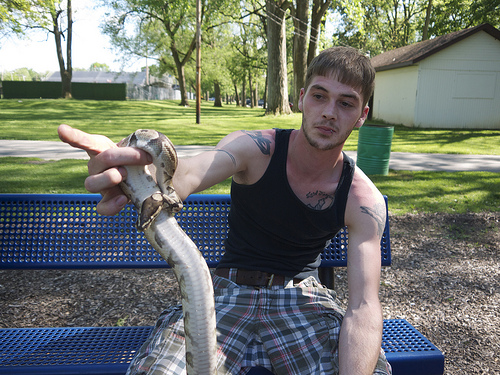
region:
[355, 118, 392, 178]
Green garbage can.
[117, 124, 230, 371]
Snake in man's hand.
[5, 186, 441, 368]
Blue park bench.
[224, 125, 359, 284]
Black tank top on man.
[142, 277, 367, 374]
Plaid shorts on man.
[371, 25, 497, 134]
Tan building in park.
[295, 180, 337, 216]
Tattoo on man's chest.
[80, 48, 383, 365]
Man holding snake in his hand.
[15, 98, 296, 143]
Green grass in park.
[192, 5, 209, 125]
Utility pole in park.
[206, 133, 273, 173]
the tattoos are black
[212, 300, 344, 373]
the shorts are plaid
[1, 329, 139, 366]
the bench is blue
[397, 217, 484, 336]
the mulch is brown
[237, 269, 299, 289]
the belt is brown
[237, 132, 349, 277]
the tank top is black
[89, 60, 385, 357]
man is holding snake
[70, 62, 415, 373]
man is sitting on bench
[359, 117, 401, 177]
the trash can is green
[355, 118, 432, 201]
trash can is in grass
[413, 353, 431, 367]
edge of a bench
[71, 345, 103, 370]
part of a bench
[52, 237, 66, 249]
a blue bench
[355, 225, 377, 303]
left arm of a man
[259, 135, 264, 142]
section of a tatoo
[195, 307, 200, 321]
a snakes body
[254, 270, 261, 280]
part of a brown belt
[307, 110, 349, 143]
face of a man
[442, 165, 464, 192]
section of a lawn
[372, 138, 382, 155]
part of a green drum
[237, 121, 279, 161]
tattoo on a shoulder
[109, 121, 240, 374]
snake in a man's hand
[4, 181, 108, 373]
blue bench in a park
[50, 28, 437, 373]
man holding a snake on a bench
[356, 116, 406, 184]
green trash can on the grass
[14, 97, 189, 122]
green grass in a park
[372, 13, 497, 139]
building in the background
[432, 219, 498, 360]
brown mulch on ground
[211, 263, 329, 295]
brown belt of a man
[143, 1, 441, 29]
green leaved trees in the distance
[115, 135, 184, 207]
a python snake coiling around a man's fingers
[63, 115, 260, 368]
a python snake being held by a man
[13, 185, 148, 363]
a blue metal bench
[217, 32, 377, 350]
a man wearing a black tank top and plaid shorts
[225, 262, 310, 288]
a brown belt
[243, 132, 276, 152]
a black tattoo on a man's right shoulder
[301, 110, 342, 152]
a brown goatee and mustache on a man's face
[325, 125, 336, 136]
a toothpick in a man's mouth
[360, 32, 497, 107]
a white shed with a brown roof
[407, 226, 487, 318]
an area of gravel and rocks